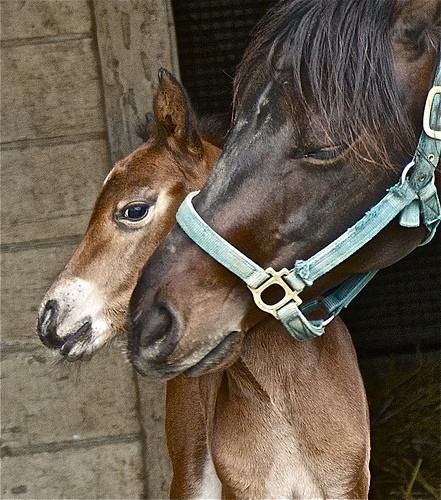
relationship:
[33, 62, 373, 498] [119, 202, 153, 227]
foal has eye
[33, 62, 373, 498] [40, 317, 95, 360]
foal has mouth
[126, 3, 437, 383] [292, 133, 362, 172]
horse has eye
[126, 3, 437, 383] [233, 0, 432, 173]
horse has mane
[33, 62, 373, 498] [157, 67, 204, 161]
foal has ears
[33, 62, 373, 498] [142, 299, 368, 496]
foal has body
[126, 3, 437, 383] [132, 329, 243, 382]
horse has mouth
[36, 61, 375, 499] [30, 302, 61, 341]
calf has nose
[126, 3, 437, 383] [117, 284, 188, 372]
horse has nose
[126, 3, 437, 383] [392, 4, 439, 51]
horse has ear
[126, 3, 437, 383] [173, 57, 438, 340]
horse has bridle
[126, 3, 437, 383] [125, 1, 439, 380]
horse has head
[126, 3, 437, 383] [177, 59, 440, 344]
horse has reigns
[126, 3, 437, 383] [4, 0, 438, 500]
horse near barn